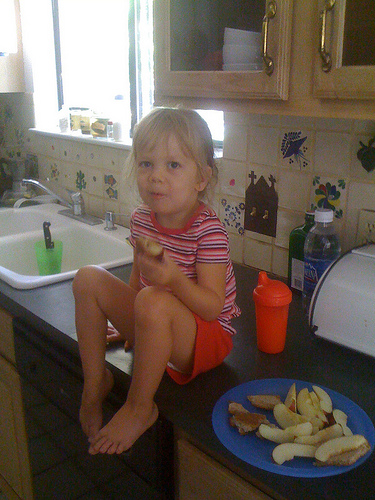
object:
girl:
[67, 104, 242, 457]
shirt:
[124, 207, 243, 339]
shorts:
[165, 318, 234, 388]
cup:
[252, 271, 291, 357]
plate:
[209, 376, 369, 482]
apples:
[270, 441, 317, 467]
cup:
[32, 237, 63, 274]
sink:
[0, 223, 132, 279]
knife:
[40, 221, 54, 245]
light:
[241, 175, 280, 241]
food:
[132, 236, 165, 265]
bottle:
[300, 204, 340, 324]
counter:
[30, 255, 375, 500]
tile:
[84, 165, 102, 201]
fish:
[104, 184, 119, 204]